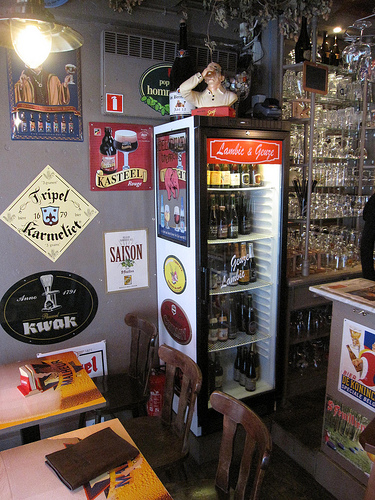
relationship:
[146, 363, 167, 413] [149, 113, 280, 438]
fire extinguisher next to fridge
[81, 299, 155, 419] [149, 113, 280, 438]
chair next to fridge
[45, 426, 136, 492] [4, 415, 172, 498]
notebook on table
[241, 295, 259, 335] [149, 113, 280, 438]
bottle in fridge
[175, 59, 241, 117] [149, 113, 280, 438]
sculpture on top of fridge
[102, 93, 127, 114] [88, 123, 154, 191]
sticker on top of poster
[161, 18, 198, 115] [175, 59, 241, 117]
bottle next to sculpture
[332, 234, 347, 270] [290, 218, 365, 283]
wine glass on shelf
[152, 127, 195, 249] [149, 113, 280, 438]
poster on fridge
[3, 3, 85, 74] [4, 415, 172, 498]
lamp above table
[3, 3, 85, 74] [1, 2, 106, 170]
lamp in corner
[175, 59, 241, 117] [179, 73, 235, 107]
sculpture wearing shirt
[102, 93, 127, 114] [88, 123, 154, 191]
sticker above poster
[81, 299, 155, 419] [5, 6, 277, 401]
chair closest to wall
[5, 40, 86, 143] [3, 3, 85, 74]
poster partially covered by lamp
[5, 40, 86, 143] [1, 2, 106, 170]
poster in corner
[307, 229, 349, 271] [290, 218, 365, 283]
wine glasses on shelf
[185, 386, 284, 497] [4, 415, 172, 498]
chair at table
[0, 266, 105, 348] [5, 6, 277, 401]
sign on wall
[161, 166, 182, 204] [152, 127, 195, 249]
elephant on poster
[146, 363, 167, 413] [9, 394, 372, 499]
fire extinguisher on floor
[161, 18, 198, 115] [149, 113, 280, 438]
bottle on top of fridge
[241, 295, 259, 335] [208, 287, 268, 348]
bottle on shelf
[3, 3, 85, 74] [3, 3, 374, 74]
lamp hanging from ceiling